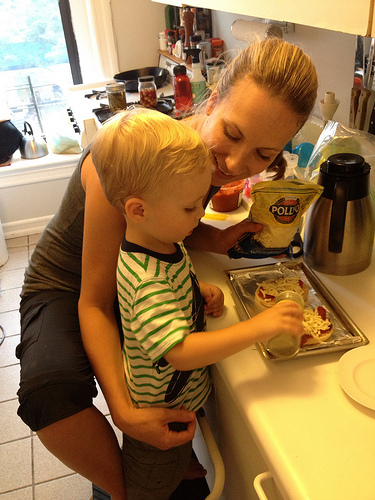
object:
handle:
[253, 470, 271, 499]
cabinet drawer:
[215, 367, 285, 500]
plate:
[336, 346, 375, 411]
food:
[255, 275, 334, 359]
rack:
[230, 18, 295, 43]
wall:
[211, 9, 357, 128]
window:
[0, 0, 103, 139]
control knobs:
[67, 107, 81, 135]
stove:
[3, 99, 103, 163]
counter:
[186, 250, 375, 500]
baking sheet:
[222, 257, 369, 362]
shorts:
[14, 290, 98, 433]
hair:
[89, 104, 217, 215]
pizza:
[300, 304, 333, 348]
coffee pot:
[303, 153, 375, 276]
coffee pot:
[19, 121, 48, 159]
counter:
[0, 130, 82, 173]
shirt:
[116, 233, 212, 413]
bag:
[249, 178, 325, 248]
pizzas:
[255, 273, 310, 307]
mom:
[15, 25, 318, 500]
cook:
[255, 275, 333, 361]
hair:
[179, 24, 318, 139]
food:
[105, 82, 127, 113]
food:
[138, 76, 157, 110]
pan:
[113, 66, 169, 92]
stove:
[60, 66, 174, 150]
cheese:
[265, 291, 305, 358]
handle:
[24, 121, 34, 137]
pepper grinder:
[171, 9, 199, 62]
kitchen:
[0, 0, 375, 500]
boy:
[90, 104, 304, 500]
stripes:
[130, 288, 181, 323]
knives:
[354, 34, 374, 89]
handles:
[349, 88, 375, 133]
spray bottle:
[183, 49, 207, 108]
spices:
[158, 5, 222, 84]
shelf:
[157, 49, 193, 80]